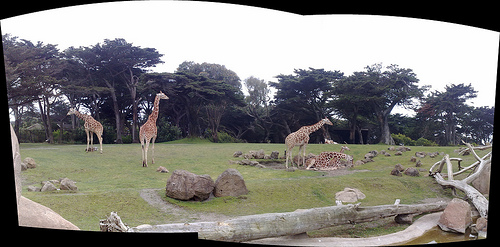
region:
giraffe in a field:
[64, 99, 109, 153]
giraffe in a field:
[126, 89, 173, 168]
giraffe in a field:
[278, 113, 334, 173]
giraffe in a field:
[309, 139, 358, 176]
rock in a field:
[210, 164, 257, 202]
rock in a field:
[160, 162, 222, 201]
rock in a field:
[59, 173, 79, 192]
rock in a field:
[154, 160, 172, 177]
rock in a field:
[21, 156, 39, 170]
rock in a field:
[322, 176, 372, 208]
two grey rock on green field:
[160, 157, 252, 205]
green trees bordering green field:
[1, 30, 443, 147]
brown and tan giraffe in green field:
[127, 82, 174, 172]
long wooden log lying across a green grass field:
[100, 194, 443, 244]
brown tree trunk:
[36, 101, 60, 143]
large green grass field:
[18, 137, 443, 227]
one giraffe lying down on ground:
[301, 148, 357, 175]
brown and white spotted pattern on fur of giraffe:
[298, 133, 307, 140]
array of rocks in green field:
[357, 141, 439, 184]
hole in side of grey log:
[383, 208, 419, 225]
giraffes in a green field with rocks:
[3, 22, 478, 235]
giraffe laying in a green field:
[301, 148, 361, 173]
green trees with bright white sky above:
[0, 21, 491, 146]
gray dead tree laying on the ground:
[430, 137, 492, 239]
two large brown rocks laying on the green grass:
[162, 169, 252, 202]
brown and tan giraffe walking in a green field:
[134, 89, 171, 165]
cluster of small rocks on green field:
[22, 172, 85, 192]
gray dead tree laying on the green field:
[102, 201, 447, 236]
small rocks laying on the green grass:
[360, 142, 439, 160]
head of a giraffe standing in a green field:
[66, 102, 78, 117]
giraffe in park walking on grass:
[62, 88, 360, 171]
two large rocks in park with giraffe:
[165, 170, 250, 200]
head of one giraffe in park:
[155, 91, 168, 99]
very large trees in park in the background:
[1, 35, 487, 141]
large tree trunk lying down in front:
[95, 198, 446, 234]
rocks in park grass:
[25, 178, 78, 193]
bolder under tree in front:
[438, 192, 469, 233]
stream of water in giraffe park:
[136, 188, 222, 218]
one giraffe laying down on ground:
[303, 150, 348, 170]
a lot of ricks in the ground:
[363, 143, 440, 175]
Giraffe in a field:
[125, 77, 172, 183]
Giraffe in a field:
[53, 89, 116, 161]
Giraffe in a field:
[266, 101, 318, 183]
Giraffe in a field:
[308, 144, 363, 174]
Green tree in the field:
[180, 51, 227, 101]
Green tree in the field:
[240, 67, 274, 117]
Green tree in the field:
[270, 62, 333, 109]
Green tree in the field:
[333, 69, 400, 120]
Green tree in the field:
[413, 83, 488, 100]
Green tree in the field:
[78, 39, 147, 100]